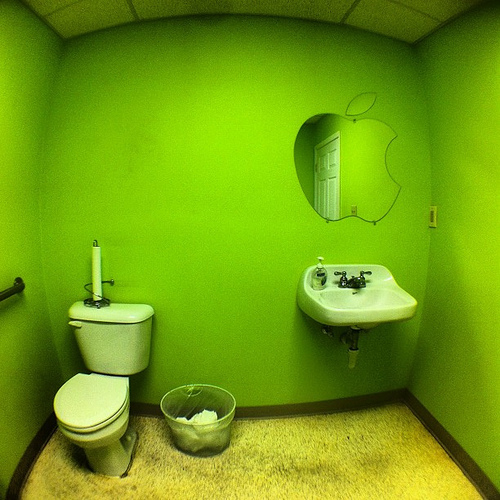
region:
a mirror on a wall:
[293, 90, 405, 225]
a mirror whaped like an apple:
[295, 91, 402, 223]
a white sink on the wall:
[302, 263, 419, 323]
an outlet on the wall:
[426, 204, 437, 227]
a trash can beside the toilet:
[161, 384, 237, 459]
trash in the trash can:
[175, 408, 224, 450]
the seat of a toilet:
[53, 372, 130, 432]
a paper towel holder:
[82, 237, 115, 309]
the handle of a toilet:
[68, 318, 83, 327]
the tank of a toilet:
[69, 300, 154, 373]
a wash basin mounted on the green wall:
[295, 252, 420, 428]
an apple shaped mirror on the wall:
[282, 65, 412, 230]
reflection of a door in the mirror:
[292, 90, 397, 222]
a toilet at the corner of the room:
[12, 240, 148, 480]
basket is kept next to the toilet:
[55, 231, 235, 476]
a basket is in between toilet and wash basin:
[50, 235, 415, 475]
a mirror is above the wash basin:
[290, 86, 415, 371]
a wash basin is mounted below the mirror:
[290, 86, 420, 371]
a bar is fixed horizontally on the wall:
[2, 230, 42, 495]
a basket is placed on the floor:
[156, 380, 241, 466]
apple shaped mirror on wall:
[275, 65, 422, 247]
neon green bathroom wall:
[50, 33, 441, 417]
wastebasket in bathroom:
[147, 368, 248, 475]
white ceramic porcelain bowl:
[37, 268, 174, 480]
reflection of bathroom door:
[270, 68, 422, 249]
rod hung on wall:
[3, 272, 38, 316]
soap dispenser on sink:
[307, 253, 334, 285]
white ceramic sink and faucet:
[297, 262, 431, 339]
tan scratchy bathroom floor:
[203, 445, 437, 496]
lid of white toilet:
[42, 369, 143, 437]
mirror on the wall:
[287, 82, 418, 227]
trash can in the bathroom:
[155, 372, 241, 460]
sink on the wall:
[289, 256, 422, 376]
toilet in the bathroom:
[47, 220, 169, 485]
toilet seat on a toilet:
[41, 365, 137, 437]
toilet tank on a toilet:
[62, 293, 164, 378]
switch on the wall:
[420, 197, 444, 242]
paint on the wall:
[43, 33, 446, 427]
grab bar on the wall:
[0, 267, 34, 302]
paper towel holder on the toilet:
[80, 233, 115, 318]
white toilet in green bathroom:
[55, 293, 155, 480]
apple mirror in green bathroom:
[289, 86, 401, 221]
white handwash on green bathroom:
[298, 260, 420, 336]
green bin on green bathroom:
[161, 385, 236, 455]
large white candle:
[89, 243, 103, 308]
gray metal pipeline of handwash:
[323, 323, 359, 365]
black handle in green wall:
[0, 275, 26, 302]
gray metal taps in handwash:
[330, 266, 377, 288]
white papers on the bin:
[166, 406, 221, 446]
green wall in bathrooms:
[1, 3, 491, 498]